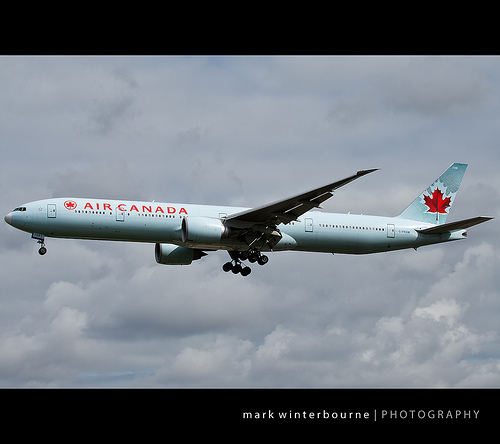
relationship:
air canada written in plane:
[83, 202, 189, 215] [7, 162, 493, 273]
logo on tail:
[421, 178, 458, 216] [393, 155, 480, 245]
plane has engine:
[7, 162, 493, 273] [179, 213, 243, 248]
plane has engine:
[7, 162, 493, 273] [159, 241, 199, 268]